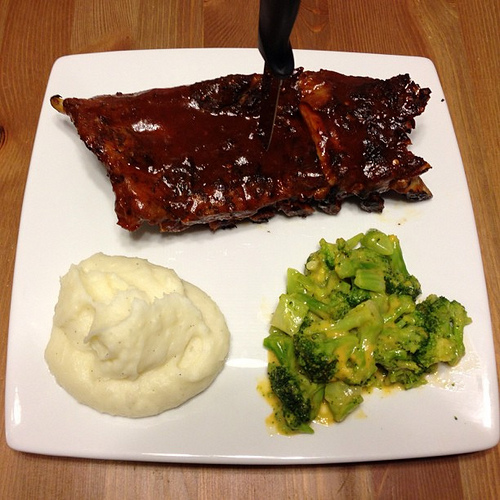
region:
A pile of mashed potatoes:
[40, 242, 237, 421]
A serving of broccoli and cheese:
[250, 220, 482, 445]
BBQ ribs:
[40, 47, 440, 235]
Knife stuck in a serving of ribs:
[242, 2, 314, 157]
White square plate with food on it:
[3, 35, 496, 412]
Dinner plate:
[7, 18, 499, 464]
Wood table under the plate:
[9, 6, 191, 41]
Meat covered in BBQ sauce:
[47, 53, 449, 230]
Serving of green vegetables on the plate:
[245, 218, 480, 437]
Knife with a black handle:
[247, 0, 306, 154]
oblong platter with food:
[15, 10, 492, 466]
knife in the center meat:
[56, 2, 418, 227]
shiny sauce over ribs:
[76, 66, 431, 223]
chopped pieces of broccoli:
[255, 235, 470, 435]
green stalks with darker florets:
[255, 230, 475, 425]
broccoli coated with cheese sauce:
[261, 235, 456, 431]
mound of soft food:
[35, 246, 230, 421]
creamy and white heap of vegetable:
[30, 246, 222, 421]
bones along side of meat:
[115, 175, 440, 236]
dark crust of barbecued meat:
[235, 70, 435, 216]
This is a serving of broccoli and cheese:
[323, 276, 380, 406]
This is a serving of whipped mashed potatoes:
[81, 293, 167, 435]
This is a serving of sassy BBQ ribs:
[145, 17, 370, 107]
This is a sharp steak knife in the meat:
[245, 0, 305, 150]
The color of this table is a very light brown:
[408, 475, 430, 497]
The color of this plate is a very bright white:
[205, 433, 231, 463]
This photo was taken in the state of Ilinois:
[88, 67, 364, 452]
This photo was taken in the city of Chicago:
[80, 102, 431, 425]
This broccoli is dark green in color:
[329, 261, 378, 376]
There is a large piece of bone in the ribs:
[43, 101, 89, 104]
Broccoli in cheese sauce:
[259, 230, 499, 445]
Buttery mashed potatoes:
[44, 233, 229, 425]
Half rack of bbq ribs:
[56, 91, 496, 231]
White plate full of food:
[4, 7, 486, 457]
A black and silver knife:
[251, 3, 301, 168]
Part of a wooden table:
[9, 7, 133, 69]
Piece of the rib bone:
[392, 164, 444, 214]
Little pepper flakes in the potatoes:
[138, 332, 183, 364]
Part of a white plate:
[5, 258, 491, 453]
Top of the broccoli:
[289, 336, 344, 386]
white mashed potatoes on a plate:
[41, 249, 237, 421]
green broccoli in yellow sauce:
[251, 222, 472, 440]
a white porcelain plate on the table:
[1, 43, 498, 470]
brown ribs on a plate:
[47, 65, 437, 247]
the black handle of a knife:
[255, 0, 307, 82]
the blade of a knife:
[250, 59, 285, 146]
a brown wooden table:
[0, 0, 499, 499]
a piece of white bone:
[45, 91, 72, 121]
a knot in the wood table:
[295, 0, 330, 36]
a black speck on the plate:
[438, 92, 447, 107]